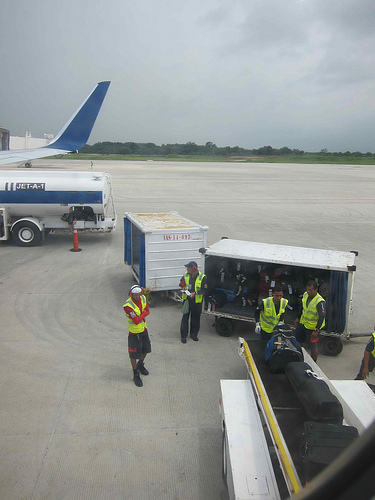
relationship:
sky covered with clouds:
[1, 0, 371, 149] [7, 7, 374, 134]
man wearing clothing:
[124, 297, 150, 335] [123, 298, 149, 334]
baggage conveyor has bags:
[239, 339, 373, 496] [265, 336, 358, 461]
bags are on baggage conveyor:
[265, 336, 358, 461] [239, 339, 373, 496]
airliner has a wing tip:
[3, 79, 116, 164] [34, 81, 117, 144]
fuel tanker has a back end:
[2, 167, 117, 243] [31, 173, 119, 239]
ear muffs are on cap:
[128, 289, 146, 292] [127, 286, 147, 295]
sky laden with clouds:
[1, 0, 371, 149] [7, 7, 374, 134]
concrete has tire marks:
[12, 243, 135, 499] [29, 257, 122, 355]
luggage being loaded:
[265, 336, 358, 461] [243, 321, 304, 342]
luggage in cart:
[223, 262, 316, 308] [198, 230, 366, 343]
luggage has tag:
[282, 358, 344, 417] [304, 369, 325, 384]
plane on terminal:
[3, 79, 116, 164] [10, 152, 371, 498]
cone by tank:
[69, 218, 85, 258] [2, 167, 117, 243]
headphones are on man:
[187, 260, 199, 276] [181, 261, 205, 344]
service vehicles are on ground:
[6, 166, 364, 341] [10, 152, 371, 498]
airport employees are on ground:
[116, 250, 331, 353] [10, 152, 371, 498]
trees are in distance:
[95, 141, 373, 164] [57, 136, 373, 164]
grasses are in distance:
[97, 151, 370, 164] [57, 136, 373, 164]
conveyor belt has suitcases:
[239, 339, 373, 496] [265, 336, 358, 461]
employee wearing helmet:
[120, 283, 159, 387] [127, 284, 142, 301]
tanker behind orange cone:
[2, 167, 117, 243] [61, 216, 89, 255]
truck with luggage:
[198, 230, 366, 343] [206, 247, 344, 328]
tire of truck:
[208, 314, 233, 333] [198, 230, 366, 343]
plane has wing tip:
[3, 79, 116, 164] [34, 81, 117, 144]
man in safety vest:
[124, 297, 150, 335] [116, 299, 152, 329]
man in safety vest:
[181, 261, 205, 344] [175, 273, 209, 304]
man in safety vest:
[256, 284, 295, 339] [255, 298, 292, 329]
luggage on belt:
[306, 423, 363, 459] [239, 339, 373, 496]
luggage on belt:
[282, 358, 344, 417] [239, 339, 373, 496]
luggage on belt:
[269, 323, 310, 364] [239, 339, 373, 496]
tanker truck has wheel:
[2, 167, 117, 243] [8, 213, 45, 247]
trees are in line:
[95, 141, 373, 164] [102, 143, 365, 156]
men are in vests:
[107, 265, 330, 328] [125, 299, 348, 326]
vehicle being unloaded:
[198, 230, 366, 343] [254, 308, 321, 351]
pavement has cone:
[10, 152, 371, 498] [69, 218, 85, 258]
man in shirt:
[124, 297, 150, 335] [123, 298, 149, 334]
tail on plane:
[42, 72, 127, 160] [3, 79, 116, 164]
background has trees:
[89, 93, 371, 163] [91, 134, 328, 159]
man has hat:
[130, 278, 152, 385] [125, 282, 147, 296]